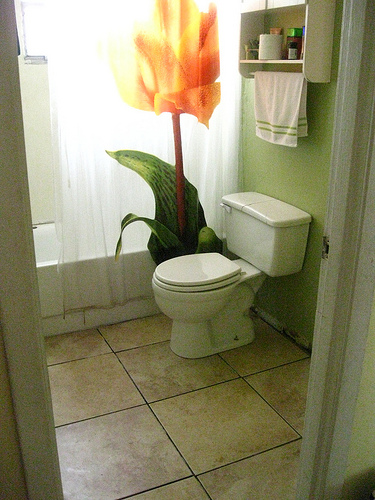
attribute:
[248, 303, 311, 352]
bottom — damaged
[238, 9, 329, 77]
shelf — white, attached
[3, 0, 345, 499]
bathroom — tulip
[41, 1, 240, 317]
curtain — bathroom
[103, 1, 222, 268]
tulip design — giant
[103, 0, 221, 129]
tulip — orange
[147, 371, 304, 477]
tile — square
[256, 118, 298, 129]
line — green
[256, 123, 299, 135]
line — green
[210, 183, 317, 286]
tank — cracked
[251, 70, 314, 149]
towel — hanging, white, green, striped, above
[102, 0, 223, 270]
tulip — large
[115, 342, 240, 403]
tile — square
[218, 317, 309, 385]
tile — square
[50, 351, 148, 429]
tile — square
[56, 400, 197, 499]
tile — square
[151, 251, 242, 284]
seat cover — toilet, down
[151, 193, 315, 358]
porcelain toilet — white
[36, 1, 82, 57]
light — shining